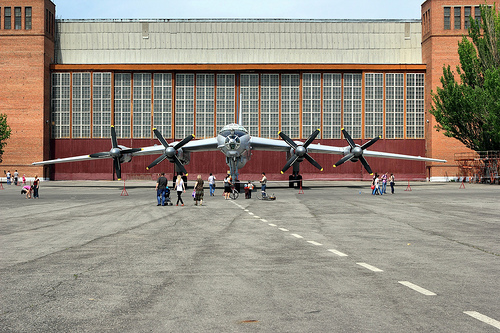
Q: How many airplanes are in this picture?
A: 1.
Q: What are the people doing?
A: Looking at airplane.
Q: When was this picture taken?
A: Daytime.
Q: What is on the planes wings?
A: Propellers.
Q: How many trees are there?
A: 2.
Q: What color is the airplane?
A: Silver.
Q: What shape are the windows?
A: Rectangle.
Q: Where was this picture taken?
A: Airport.